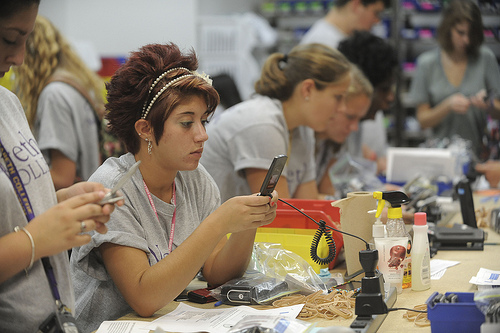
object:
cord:
[277, 198, 370, 265]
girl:
[0, 1, 126, 331]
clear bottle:
[410, 225, 432, 292]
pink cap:
[412, 211, 426, 226]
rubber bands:
[270, 287, 354, 321]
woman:
[68, 39, 278, 333]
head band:
[140, 67, 213, 119]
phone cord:
[256, 154, 384, 291]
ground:
[372, 190, 410, 237]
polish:
[409, 212, 430, 291]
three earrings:
[137, 133, 152, 155]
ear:
[135, 120, 151, 141]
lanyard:
[142, 177, 177, 254]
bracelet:
[14, 225, 36, 270]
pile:
[271, 289, 356, 320]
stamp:
[354, 249, 386, 314]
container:
[425, 291, 488, 332]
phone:
[257, 154, 289, 200]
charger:
[263, 191, 389, 314]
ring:
[80, 221, 85, 229]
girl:
[67, 44, 279, 333]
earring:
[148, 139, 153, 154]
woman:
[407, 0, 499, 159]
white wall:
[41, 0, 193, 57]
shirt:
[405, 45, 499, 161]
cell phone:
[257, 153, 291, 197]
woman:
[0, 0, 125, 333]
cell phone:
[100, 159, 140, 204]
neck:
[134, 140, 178, 193]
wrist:
[1, 219, 39, 282]